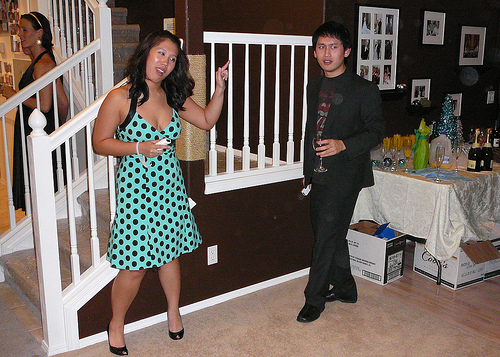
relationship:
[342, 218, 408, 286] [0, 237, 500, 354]
cardboard box on floor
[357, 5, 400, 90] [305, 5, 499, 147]
picture on wall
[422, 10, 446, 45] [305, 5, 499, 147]
picture on wall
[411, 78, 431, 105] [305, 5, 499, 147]
picture on wall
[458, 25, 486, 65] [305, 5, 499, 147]
picture on wall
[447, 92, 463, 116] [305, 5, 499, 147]
picture on wall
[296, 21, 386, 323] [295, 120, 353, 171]
boy holding glass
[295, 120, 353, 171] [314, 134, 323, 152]
glass of wine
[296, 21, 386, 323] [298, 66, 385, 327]
boy wearing suit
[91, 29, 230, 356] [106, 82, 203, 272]
girl wearing dress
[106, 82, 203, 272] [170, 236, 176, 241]
dress with polka dot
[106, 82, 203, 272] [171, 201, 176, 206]
dress with polka dot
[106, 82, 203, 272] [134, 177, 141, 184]
dress with polka dot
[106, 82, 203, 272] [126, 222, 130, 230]
dress with polka dot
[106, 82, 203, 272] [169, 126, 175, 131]
dress with polka dot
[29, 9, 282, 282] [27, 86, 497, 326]
stairs leading to basement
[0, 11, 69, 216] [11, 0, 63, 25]
girl wearing headband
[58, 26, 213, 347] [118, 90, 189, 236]
girl wearing dress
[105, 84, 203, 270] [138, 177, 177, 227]
dress with dots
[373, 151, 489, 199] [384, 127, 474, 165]
table top of refreshments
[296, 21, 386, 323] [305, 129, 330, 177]
boy holding glass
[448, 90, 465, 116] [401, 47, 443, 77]
picture on wall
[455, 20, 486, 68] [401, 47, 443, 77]
picture on wall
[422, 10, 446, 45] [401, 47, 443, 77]
picture on wall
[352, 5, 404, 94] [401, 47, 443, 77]
picture on wall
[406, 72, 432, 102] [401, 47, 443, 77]
picture on wall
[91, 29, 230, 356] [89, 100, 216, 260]
girl wearing dress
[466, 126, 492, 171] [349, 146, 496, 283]
item on table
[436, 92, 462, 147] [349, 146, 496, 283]
item on table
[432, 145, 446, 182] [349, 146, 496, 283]
item on table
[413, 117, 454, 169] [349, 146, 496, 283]
item on table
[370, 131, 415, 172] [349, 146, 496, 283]
item on table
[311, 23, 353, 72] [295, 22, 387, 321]
head of boy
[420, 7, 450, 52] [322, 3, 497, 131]
picture on wall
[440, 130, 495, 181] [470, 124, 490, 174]
bottles of champagne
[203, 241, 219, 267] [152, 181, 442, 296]
panel on wall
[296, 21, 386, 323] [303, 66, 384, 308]
boy in a suit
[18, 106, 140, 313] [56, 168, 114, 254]
railing on steps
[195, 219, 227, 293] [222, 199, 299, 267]
outlet on wall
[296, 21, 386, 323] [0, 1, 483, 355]
boy in basement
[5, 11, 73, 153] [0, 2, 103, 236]
girl in background